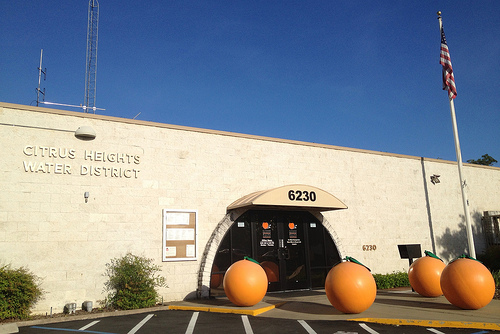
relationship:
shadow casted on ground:
[384, 283, 451, 316] [285, 302, 497, 332]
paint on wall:
[23, 200, 69, 228] [0, 112, 197, 302]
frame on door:
[244, 210, 304, 224] [235, 208, 328, 288]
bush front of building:
[100, 250, 165, 310] [0, 101, 497, 320]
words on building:
[21, 135, 144, 180] [0, 101, 497, 320]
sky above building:
[176, 29, 296, 103] [0, 101, 497, 320]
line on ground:
[186, 309, 198, 332] [3, 299, 498, 330]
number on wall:
[361, 242, 377, 251] [1, 105, 496, 315]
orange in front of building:
[447, 257, 488, 312] [33, 69, 465, 329]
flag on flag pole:
[393, 23, 491, 107] [430, 10, 477, 263]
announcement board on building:
[160, 208, 198, 261] [33, 69, 465, 329]